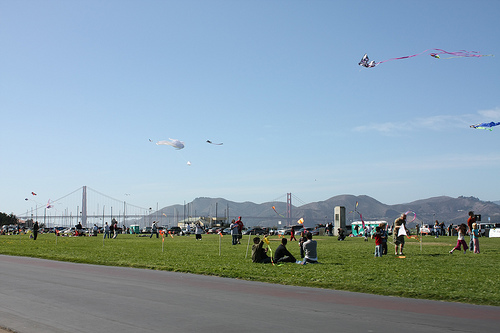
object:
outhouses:
[351, 220, 389, 237]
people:
[0, 209, 500, 265]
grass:
[0, 232, 500, 308]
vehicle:
[277, 224, 304, 236]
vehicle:
[58, 226, 89, 233]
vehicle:
[419, 224, 434, 235]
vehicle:
[167, 226, 181, 234]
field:
[0, 225, 500, 307]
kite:
[357, 44, 496, 69]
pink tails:
[377, 46, 500, 65]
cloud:
[338, 107, 498, 147]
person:
[195, 222, 207, 241]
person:
[472, 222, 482, 255]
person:
[467, 211, 482, 253]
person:
[449, 223, 470, 255]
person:
[392, 213, 410, 255]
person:
[373, 232, 382, 258]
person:
[379, 222, 389, 255]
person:
[298, 231, 307, 258]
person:
[251, 234, 275, 264]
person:
[289, 227, 296, 241]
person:
[234, 215, 245, 244]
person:
[150, 221, 161, 239]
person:
[103, 222, 110, 239]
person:
[33, 220, 39, 240]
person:
[229, 218, 240, 245]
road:
[0, 250, 500, 333]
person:
[300, 232, 319, 265]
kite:
[147, 137, 192, 167]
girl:
[449, 223, 469, 254]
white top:
[458, 230, 465, 240]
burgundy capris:
[455, 239, 469, 251]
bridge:
[11, 186, 351, 229]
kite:
[469, 121, 500, 133]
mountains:
[115, 193, 499, 231]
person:
[273, 237, 296, 264]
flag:
[159, 229, 174, 252]